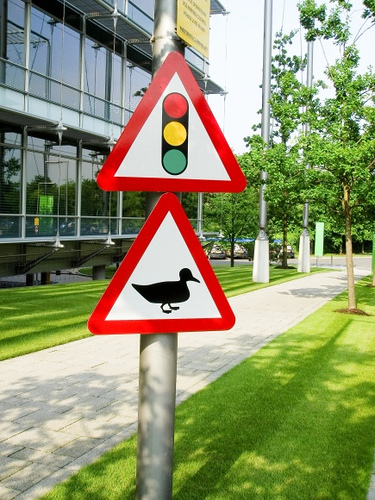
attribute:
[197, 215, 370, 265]
lot — parking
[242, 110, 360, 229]
tree — young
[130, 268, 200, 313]
duck — black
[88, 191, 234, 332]
sign — triangle, red and white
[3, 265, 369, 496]
sidewalk — made with pavers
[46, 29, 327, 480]
signs — triangle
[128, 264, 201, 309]
duck — red and white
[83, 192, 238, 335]
duck sign — black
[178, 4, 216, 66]
sign — yellow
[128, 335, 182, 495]
pole — grey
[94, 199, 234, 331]
sign — red and white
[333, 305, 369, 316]
mulch — brown 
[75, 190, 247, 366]
sign — white